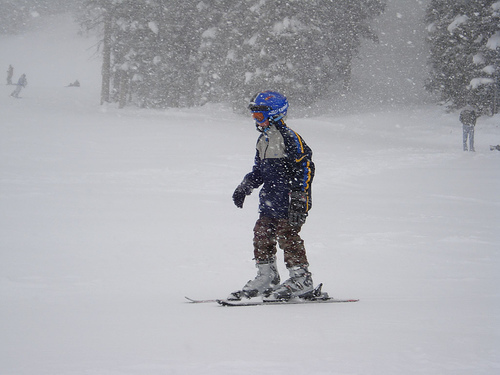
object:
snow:
[371, 20, 431, 98]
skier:
[223, 87, 325, 309]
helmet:
[248, 83, 292, 124]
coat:
[238, 120, 316, 226]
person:
[456, 98, 484, 151]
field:
[0, 96, 497, 365]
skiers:
[9, 72, 29, 100]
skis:
[218, 292, 361, 312]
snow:
[441, 13, 472, 37]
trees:
[103, 0, 380, 109]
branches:
[430, 10, 498, 40]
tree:
[424, 2, 499, 110]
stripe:
[290, 131, 314, 199]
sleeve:
[282, 132, 320, 213]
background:
[4, 57, 103, 61]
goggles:
[248, 103, 291, 118]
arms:
[290, 135, 319, 196]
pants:
[250, 192, 316, 266]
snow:
[104, 219, 461, 352]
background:
[360, 71, 426, 76]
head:
[462, 99, 476, 108]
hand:
[231, 183, 249, 210]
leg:
[272, 213, 316, 276]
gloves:
[283, 199, 312, 233]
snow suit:
[232, 127, 315, 275]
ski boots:
[258, 259, 329, 305]